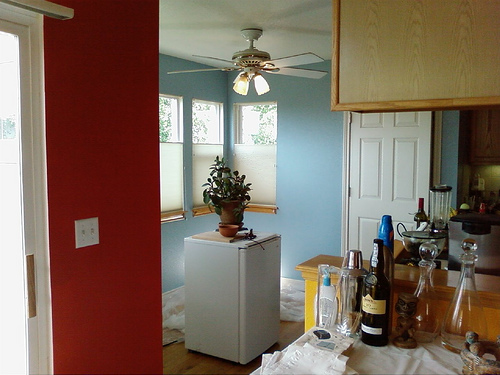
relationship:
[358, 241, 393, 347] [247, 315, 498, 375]
bottle on table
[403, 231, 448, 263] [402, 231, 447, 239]
bowl has lid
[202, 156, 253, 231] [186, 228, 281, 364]
plant on fridge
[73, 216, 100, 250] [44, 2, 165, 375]
switch on wall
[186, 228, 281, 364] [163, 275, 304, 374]
fridge on floor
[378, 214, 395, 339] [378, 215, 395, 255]
bottle with lid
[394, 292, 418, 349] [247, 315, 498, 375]
knick knack on table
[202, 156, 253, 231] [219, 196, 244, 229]
plant in planter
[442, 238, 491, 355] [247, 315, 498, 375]
glass on table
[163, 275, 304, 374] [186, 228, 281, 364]
floor by fridge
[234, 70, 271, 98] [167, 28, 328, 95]
lights on fan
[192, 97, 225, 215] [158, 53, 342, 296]
window on wall